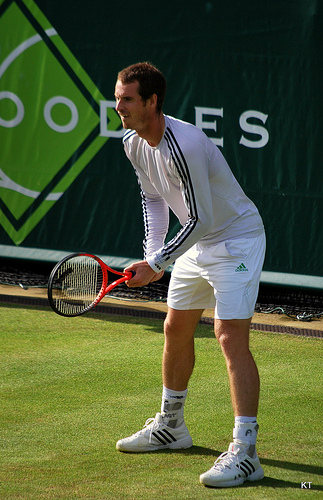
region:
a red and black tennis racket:
[39, 247, 133, 317]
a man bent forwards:
[41, 56, 276, 489]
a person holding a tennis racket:
[32, 51, 281, 493]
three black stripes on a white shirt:
[156, 128, 201, 265]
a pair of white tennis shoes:
[113, 415, 266, 490]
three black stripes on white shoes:
[152, 429, 178, 447]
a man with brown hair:
[106, 59, 163, 145]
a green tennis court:
[0, 302, 321, 498]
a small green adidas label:
[235, 258, 249, 276]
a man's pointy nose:
[116, 95, 125, 113]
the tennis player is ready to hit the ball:
[42, 60, 272, 490]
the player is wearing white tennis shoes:
[116, 411, 266, 484]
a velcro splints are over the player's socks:
[158, 385, 259, 448]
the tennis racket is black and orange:
[44, 250, 163, 315]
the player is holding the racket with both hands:
[44, 247, 167, 316]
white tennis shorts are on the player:
[169, 231, 265, 316]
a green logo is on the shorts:
[228, 257, 252, 275]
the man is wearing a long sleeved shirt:
[112, 114, 264, 269]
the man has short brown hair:
[109, 60, 164, 137]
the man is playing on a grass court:
[2, 299, 314, 495]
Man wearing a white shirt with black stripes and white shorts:
[78, 52, 276, 486]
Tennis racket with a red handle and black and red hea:
[40, 232, 141, 325]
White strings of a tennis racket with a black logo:
[59, 260, 97, 305]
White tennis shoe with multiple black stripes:
[205, 443, 265, 488]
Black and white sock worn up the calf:
[227, 403, 261, 448]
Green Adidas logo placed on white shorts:
[230, 254, 253, 277]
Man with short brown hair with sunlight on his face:
[106, 56, 168, 135]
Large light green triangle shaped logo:
[2, 1, 123, 261]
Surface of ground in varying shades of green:
[15, 341, 121, 466]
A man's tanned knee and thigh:
[160, 304, 198, 367]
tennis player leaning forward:
[63, 56, 274, 483]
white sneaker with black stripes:
[119, 416, 190, 453]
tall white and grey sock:
[158, 384, 187, 427]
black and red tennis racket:
[43, 252, 134, 319]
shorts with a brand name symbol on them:
[166, 230, 264, 318]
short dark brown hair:
[115, 56, 165, 127]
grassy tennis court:
[13, 314, 277, 492]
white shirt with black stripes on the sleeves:
[113, 120, 263, 265]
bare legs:
[158, 308, 265, 423]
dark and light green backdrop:
[9, 22, 311, 271]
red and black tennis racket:
[46, 251, 140, 317]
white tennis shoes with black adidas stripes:
[110, 420, 269, 488]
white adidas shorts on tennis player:
[164, 229, 269, 327]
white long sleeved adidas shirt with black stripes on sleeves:
[116, 114, 266, 274]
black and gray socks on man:
[156, 387, 267, 454]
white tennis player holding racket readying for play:
[48, 58, 275, 490]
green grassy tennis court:
[1, 307, 322, 495]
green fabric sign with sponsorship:
[4, 0, 315, 294]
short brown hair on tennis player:
[111, 61, 170, 146]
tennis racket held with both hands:
[46, 237, 165, 315]